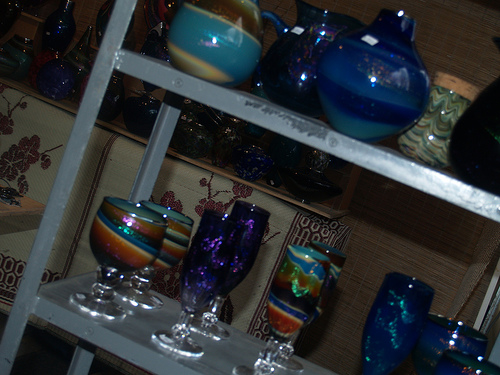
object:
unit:
[1, 1, 498, 375]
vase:
[309, 5, 432, 147]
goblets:
[260, 243, 328, 366]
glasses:
[210, 198, 268, 366]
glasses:
[181, 196, 246, 358]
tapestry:
[1, 88, 352, 372]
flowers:
[1, 140, 31, 185]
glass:
[397, 84, 475, 174]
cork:
[429, 68, 482, 105]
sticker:
[358, 32, 378, 50]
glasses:
[60, 194, 167, 329]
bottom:
[147, 325, 208, 362]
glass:
[165, 0, 272, 91]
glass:
[34, 59, 76, 103]